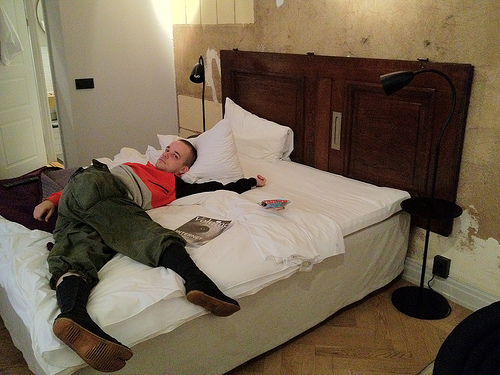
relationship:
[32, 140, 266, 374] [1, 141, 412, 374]
man drapped across bed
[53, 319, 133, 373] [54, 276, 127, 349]
sole of left shoe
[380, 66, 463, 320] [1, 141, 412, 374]
lamp beside bed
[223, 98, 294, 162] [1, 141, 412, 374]
pillow on bed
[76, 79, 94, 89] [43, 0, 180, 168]
switch on wall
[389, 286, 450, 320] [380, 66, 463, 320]
base of lamp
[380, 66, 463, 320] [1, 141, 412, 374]
lamp by bed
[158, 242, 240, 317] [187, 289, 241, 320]
right shoe on foot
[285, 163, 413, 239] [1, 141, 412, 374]
matress on bed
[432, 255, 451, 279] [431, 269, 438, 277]
plug in outlet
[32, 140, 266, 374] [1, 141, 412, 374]
man on bed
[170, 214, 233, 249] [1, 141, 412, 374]
magazine on bed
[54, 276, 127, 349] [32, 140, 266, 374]
left shoe on man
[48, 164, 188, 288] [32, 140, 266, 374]
pants on legs of man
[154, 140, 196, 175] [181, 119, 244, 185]
head on pillow